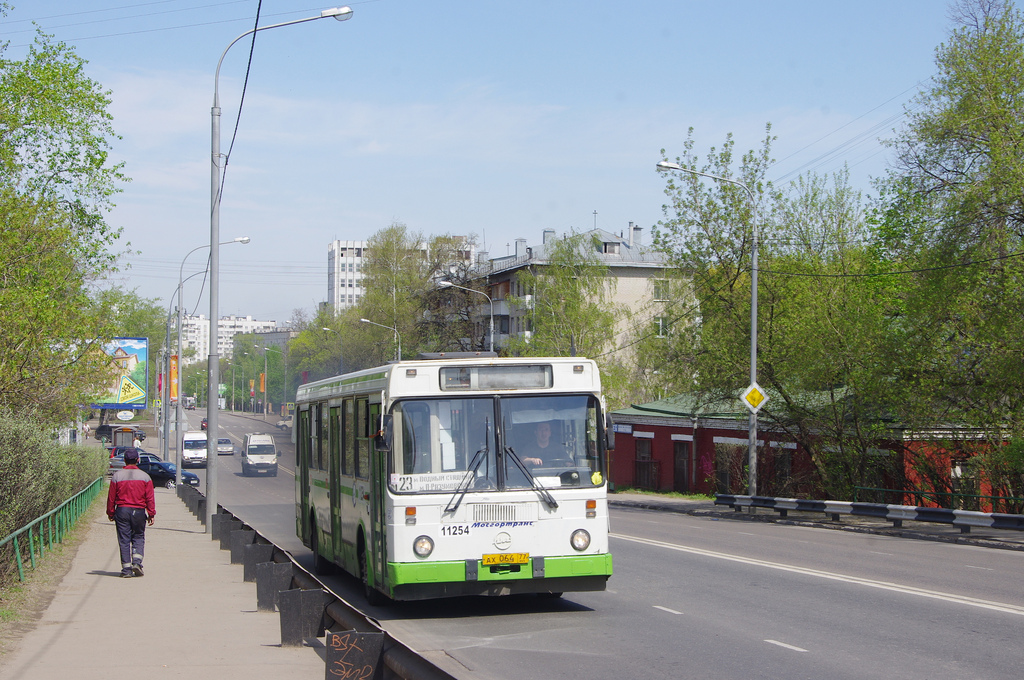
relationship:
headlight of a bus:
[564, 524, 600, 555] [276, 353, 629, 611]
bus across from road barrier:
[276, 353, 629, 611] [699, 479, 1021, 552]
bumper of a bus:
[383, 540, 614, 597] [276, 353, 629, 611]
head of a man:
[117, 446, 142, 471] [100, 446, 165, 580]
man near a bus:
[100, 446, 165, 580] [276, 353, 629, 611]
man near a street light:
[100, 446, 165, 580] [193, 1, 354, 541]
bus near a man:
[276, 353, 629, 611] [100, 446, 165, 580]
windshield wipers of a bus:
[436, 445, 560, 518] [276, 353, 629, 611]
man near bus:
[100, 446, 165, 580] [276, 353, 629, 611]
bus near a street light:
[276, 353, 629, 611] [193, 1, 354, 541]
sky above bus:
[5, 4, 988, 320] [276, 353, 629, 611]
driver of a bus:
[515, 424, 574, 473] [276, 353, 629, 611]